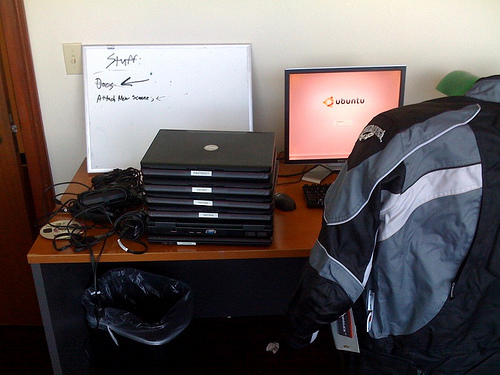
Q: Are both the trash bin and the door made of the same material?
A: No, the trash bin is made of plastic and the door is made of wood.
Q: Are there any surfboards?
A: No, there are no surfboards.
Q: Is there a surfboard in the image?
A: No, there are no surfboards.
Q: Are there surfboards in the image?
A: No, there are no surfboards.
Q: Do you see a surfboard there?
A: No, there are no surfboards.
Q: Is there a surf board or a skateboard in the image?
A: No, there are no surfboards or skateboards.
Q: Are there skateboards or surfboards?
A: No, there are no surfboards or skateboards.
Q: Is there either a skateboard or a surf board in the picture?
A: No, there are no surfboards or skateboards.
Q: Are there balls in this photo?
A: No, there are no balls.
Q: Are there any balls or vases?
A: No, there are no balls or vases.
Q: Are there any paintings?
A: No, there are no paintings.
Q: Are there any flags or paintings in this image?
A: No, there are no paintings or flags.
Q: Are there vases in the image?
A: No, there are no vases.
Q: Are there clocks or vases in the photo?
A: No, there are no vases or clocks.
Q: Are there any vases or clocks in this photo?
A: No, there are no vases or clocks.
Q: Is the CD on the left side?
A: Yes, the CD is on the left of the image.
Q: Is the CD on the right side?
A: No, the CD is on the left of the image.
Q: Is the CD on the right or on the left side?
A: The CD is on the left of the image.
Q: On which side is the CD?
A: The CD is on the left of the image.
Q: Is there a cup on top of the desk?
A: No, there is a CD on top of the desk.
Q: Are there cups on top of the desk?
A: No, there is a CD on top of the desk.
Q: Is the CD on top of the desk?
A: Yes, the CD is on top of the desk.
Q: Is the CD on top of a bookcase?
A: No, the CD is on top of the desk.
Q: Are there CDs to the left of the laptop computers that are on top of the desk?
A: Yes, there is a CD to the left of the laptops.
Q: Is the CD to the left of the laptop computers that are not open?
A: Yes, the CD is to the left of the laptops.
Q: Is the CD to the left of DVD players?
A: No, the CD is to the left of the laptops.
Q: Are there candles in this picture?
A: No, there are no candles.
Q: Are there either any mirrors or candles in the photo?
A: No, there are no candles or mirrors.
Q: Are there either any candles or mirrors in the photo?
A: No, there are no candles or mirrors.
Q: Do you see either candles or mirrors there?
A: No, there are no candles or mirrors.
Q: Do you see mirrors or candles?
A: No, there are no candles or mirrors.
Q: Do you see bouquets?
A: No, there are no bouquets.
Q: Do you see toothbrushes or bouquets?
A: No, there are no bouquets or toothbrushes.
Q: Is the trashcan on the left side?
A: Yes, the trashcan is on the left of the image.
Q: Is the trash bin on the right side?
A: No, the trash bin is on the left of the image.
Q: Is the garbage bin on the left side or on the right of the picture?
A: The garbage bin is on the left of the image.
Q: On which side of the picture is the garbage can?
A: The garbage can is on the left of the image.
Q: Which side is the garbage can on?
A: The garbage can is on the left of the image.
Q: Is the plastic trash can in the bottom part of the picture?
A: Yes, the garbage bin is in the bottom of the image.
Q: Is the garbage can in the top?
A: No, the garbage can is in the bottom of the image.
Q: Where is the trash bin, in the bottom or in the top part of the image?
A: The trash bin is in the bottom of the image.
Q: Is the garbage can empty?
A: Yes, the garbage can is empty.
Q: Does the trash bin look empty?
A: Yes, the trash bin is empty.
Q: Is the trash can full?
A: No, the trash can is empty.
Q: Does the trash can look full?
A: No, the trash can is empty.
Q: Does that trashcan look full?
A: No, the trashcan is empty.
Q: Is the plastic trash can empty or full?
A: The trashcan is empty.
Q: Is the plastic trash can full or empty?
A: The trashcan is empty.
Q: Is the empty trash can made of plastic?
A: Yes, the garbage can is made of plastic.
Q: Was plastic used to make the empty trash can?
A: Yes, the garbage can is made of plastic.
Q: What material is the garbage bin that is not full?
A: The garbage bin is made of plastic.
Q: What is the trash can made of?
A: The garbage bin is made of plastic.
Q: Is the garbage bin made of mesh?
A: No, the garbage bin is made of plastic.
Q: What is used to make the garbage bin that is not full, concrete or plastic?
A: The trash can is made of plastic.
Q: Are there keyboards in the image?
A: Yes, there is a keyboard.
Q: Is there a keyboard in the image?
A: Yes, there is a keyboard.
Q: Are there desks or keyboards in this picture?
A: Yes, there is a keyboard.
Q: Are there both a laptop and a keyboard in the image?
A: Yes, there are both a keyboard and a laptop.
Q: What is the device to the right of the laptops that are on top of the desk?
A: The device is a keyboard.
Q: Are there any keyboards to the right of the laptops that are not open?
A: Yes, there is a keyboard to the right of the laptop computers.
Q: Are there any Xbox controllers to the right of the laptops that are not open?
A: No, there is a keyboard to the right of the laptops.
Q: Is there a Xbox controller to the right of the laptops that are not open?
A: No, there is a keyboard to the right of the laptops.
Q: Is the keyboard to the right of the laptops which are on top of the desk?
A: Yes, the keyboard is to the right of the laptop computers.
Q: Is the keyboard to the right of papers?
A: No, the keyboard is to the right of the laptop computers.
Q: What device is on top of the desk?
A: The device is a keyboard.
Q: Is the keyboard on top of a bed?
A: No, the keyboard is on top of the desk.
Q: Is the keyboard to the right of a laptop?
A: Yes, the keyboard is to the right of a laptop.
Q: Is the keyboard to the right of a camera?
A: No, the keyboard is to the right of a laptop.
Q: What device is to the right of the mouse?
A: The device is a keyboard.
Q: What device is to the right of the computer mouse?
A: The device is a keyboard.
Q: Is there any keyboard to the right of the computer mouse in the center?
A: Yes, there is a keyboard to the right of the mouse.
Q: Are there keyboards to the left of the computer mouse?
A: No, the keyboard is to the right of the computer mouse.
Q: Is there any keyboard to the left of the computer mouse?
A: No, the keyboard is to the right of the computer mouse.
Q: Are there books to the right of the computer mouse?
A: No, there is a keyboard to the right of the computer mouse.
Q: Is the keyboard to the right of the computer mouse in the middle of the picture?
A: Yes, the keyboard is to the right of the computer mouse.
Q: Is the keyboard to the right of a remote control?
A: No, the keyboard is to the right of the computer mouse.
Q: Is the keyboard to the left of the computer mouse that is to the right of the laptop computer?
A: No, the keyboard is to the right of the mouse.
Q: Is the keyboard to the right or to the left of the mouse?
A: The keyboard is to the right of the mouse.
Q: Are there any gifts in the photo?
A: No, there are no gifts.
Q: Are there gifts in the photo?
A: No, there are no gifts.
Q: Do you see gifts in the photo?
A: No, there are no gifts.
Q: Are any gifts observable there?
A: No, there are no gifts.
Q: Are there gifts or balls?
A: No, there are no gifts or balls.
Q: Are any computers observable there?
A: Yes, there is a computer.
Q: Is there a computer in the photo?
A: Yes, there is a computer.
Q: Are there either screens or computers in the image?
A: Yes, there is a computer.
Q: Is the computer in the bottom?
A: Yes, the computer is in the bottom of the image.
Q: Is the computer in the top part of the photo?
A: No, the computer is in the bottom of the image.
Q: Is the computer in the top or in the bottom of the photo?
A: The computer is in the bottom of the image.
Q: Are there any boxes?
A: No, there are no boxes.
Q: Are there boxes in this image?
A: No, there are no boxes.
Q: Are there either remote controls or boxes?
A: No, there are no boxes or remote controls.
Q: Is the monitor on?
A: Yes, the monitor is on.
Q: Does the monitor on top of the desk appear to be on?
A: Yes, the monitor is on.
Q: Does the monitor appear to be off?
A: No, the monitor is on.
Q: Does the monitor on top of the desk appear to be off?
A: No, the monitor is on.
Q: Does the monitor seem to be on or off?
A: The monitor is on.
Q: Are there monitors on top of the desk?
A: Yes, there is a monitor on top of the desk.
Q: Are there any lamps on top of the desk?
A: No, there is a monitor on top of the desk.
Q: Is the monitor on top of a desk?
A: Yes, the monitor is on top of a desk.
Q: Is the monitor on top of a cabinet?
A: No, the monitor is on top of a desk.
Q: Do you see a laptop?
A: Yes, there are laptops.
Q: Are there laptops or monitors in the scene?
A: Yes, there are laptops.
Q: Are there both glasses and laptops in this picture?
A: No, there are laptops but no glasses.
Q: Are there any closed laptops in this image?
A: Yes, there are closed laptops.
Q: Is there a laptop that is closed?
A: Yes, there are laptops that are closed.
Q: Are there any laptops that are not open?
A: Yes, there are closed laptops.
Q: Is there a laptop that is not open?
A: Yes, there are closed laptops.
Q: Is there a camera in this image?
A: No, there are no cameras.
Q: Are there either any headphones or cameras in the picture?
A: No, there are no cameras or headphones.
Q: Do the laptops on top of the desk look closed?
A: Yes, the laptop computers are closed.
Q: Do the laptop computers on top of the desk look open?
A: No, the laptops are closed.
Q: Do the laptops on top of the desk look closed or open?
A: The laptops are closed.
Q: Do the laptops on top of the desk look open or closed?
A: The laptops are closed.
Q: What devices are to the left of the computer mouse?
A: The devices are laptops.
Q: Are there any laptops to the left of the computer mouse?
A: Yes, there are laptops to the left of the computer mouse.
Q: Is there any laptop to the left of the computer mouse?
A: Yes, there are laptops to the left of the computer mouse.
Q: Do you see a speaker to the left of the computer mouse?
A: No, there are laptops to the left of the computer mouse.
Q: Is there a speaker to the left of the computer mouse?
A: No, there are laptops to the left of the computer mouse.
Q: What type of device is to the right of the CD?
A: The devices are laptops.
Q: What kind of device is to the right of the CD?
A: The devices are laptops.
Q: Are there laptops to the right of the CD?
A: Yes, there are laptops to the right of the CD.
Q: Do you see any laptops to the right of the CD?
A: Yes, there are laptops to the right of the CD.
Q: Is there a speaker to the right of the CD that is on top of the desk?
A: No, there are laptops to the right of the CD.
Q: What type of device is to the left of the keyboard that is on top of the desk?
A: The devices are laptops.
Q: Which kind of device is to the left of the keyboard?
A: The devices are laptops.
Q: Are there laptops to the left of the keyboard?
A: Yes, there are laptops to the left of the keyboard.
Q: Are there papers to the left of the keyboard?
A: No, there are laptops to the left of the keyboard.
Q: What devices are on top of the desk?
A: The devices are laptops.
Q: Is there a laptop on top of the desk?
A: Yes, there are laptops on top of the desk.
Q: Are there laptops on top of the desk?
A: Yes, there are laptops on top of the desk.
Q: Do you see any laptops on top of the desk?
A: Yes, there are laptops on top of the desk.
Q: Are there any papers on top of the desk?
A: No, there are laptops on top of the desk.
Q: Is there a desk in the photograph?
A: Yes, there is a desk.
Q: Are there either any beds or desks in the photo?
A: Yes, there is a desk.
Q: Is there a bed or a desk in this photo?
A: Yes, there is a desk.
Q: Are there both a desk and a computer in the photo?
A: Yes, there are both a desk and a computer.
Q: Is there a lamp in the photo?
A: No, there are no lamps.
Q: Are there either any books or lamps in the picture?
A: No, there are no lamps or books.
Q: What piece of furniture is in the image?
A: The piece of furniture is a desk.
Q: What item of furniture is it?
A: The piece of furniture is a desk.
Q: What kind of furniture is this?
A: This is a desk.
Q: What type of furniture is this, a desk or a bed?
A: This is a desk.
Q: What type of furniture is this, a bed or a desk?
A: This is a desk.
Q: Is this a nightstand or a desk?
A: This is a desk.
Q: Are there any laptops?
A: Yes, there is a laptop.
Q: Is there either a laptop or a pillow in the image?
A: Yes, there is a laptop.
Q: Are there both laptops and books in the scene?
A: No, there is a laptop but no books.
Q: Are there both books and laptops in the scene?
A: No, there is a laptop but no books.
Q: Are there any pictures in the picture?
A: No, there are no pictures.